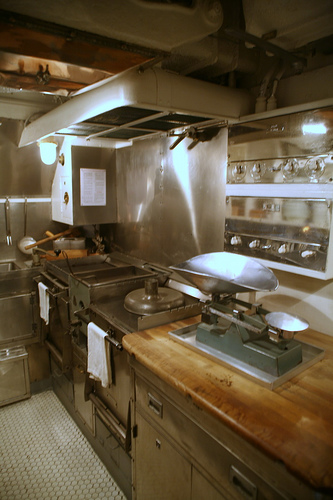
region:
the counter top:
[210, 331, 277, 453]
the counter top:
[240, 387, 287, 478]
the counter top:
[244, 389, 271, 442]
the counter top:
[230, 394, 255, 431]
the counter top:
[251, 391, 275, 466]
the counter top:
[253, 316, 299, 488]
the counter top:
[177, 316, 292, 495]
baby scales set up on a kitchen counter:
[162, 245, 322, 387]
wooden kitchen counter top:
[118, 296, 327, 492]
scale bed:
[166, 245, 276, 291]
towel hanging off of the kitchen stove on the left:
[73, 314, 111, 383]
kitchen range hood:
[16, 61, 249, 159]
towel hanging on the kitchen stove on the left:
[32, 276, 48, 325]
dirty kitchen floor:
[7, 408, 78, 496]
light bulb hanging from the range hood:
[33, 137, 63, 166]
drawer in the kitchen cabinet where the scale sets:
[135, 371, 275, 499]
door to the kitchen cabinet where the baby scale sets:
[134, 410, 195, 498]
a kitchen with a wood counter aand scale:
[2, 191, 329, 498]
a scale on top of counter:
[151, 254, 317, 394]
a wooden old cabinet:
[93, 360, 324, 498]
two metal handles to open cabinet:
[141, 393, 272, 497]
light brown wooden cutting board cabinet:
[103, 332, 331, 473]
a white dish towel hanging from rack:
[72, 322, 111, 392]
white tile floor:
[6, 398, 95, 497]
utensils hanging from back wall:
[3, 195, 34, 252]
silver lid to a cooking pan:
[114, 275, 182, 322]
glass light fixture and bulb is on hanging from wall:
[39, 140, 70, 171]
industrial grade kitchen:
[4, 62, 331, 489]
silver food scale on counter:
[173, 238, 314, 396]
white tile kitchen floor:
[8, 414, 75, 493]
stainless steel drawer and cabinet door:
[136, 372, 265, 497]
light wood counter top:
[231, 369, 325, 443]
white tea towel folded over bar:
[83, 318, 114, 395]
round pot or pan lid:
[120, 272, 185, 319]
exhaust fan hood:
[20, 47, 242, 166]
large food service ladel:
[13, 191, 40, 265]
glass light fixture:
[32, 137, 61, 173]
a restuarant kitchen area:
[17, 87, 296, 286]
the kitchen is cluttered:
[14, 99, 240, 334]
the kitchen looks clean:
[117, 233, 331, 393]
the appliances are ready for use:
[59, 306, 327, 498]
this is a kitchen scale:
[144, 246, 319, 390]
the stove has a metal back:
[70, 138, 328, 283]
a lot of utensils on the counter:
[6, 196, 100, 309]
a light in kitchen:
[12, 120, 90, 187]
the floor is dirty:
[5, 388, 134, 499]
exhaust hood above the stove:
[10, 17, 306, 123]